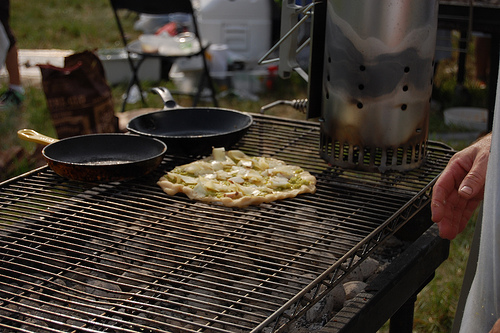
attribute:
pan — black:
[13, 121, 182, 185]